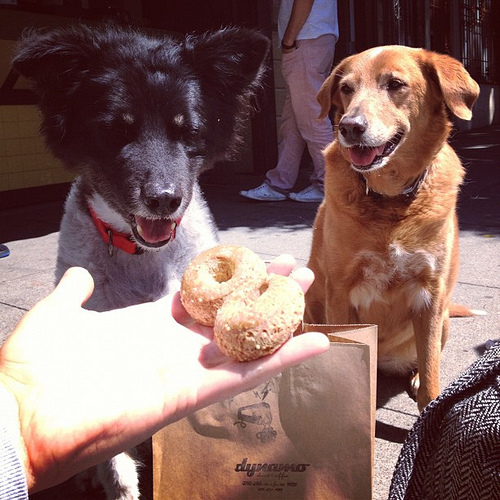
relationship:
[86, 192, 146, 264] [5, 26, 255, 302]
collar on dog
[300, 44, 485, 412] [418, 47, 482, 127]
dog with h ear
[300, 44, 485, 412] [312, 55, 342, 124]
dog with h ear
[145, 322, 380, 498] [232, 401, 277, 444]
bag with a logo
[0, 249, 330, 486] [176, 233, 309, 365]
hand with dog treats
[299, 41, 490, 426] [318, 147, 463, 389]
dog with fur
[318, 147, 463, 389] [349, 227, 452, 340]
fur on its chest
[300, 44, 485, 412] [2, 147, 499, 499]
dog sitting on a sidewalk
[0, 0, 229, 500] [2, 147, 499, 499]
dog sitting on a sidewalk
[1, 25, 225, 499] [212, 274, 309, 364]
dog looking at donut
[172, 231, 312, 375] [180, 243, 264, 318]
donut looking at donut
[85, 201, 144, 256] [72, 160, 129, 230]
collar around dog's neck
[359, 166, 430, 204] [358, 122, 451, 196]
collar around dog's neck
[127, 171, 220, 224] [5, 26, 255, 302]
nose of a dog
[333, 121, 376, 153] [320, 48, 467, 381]
nose of a dog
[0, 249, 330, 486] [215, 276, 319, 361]
hand holding donut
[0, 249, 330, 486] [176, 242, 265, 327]
hand holding donut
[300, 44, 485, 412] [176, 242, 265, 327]
dog looking at donut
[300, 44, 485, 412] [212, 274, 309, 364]
dog looking at donut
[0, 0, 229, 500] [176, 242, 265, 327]
dog looking at donut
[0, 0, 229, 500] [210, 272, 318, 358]
dog looking at donut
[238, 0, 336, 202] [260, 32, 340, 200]
man wearing brown pants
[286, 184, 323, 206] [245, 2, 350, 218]
shoe on man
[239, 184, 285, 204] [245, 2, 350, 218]
shoe on man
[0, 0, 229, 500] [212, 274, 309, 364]
dog looking at donut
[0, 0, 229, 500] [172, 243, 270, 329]
dog looking at donut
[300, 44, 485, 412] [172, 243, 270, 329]
dog looking at donut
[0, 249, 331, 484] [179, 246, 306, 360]
hand holding food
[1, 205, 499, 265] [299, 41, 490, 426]
shadow line behind dog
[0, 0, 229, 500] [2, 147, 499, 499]
dog on sidewalk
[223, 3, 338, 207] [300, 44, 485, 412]
man walking behind dog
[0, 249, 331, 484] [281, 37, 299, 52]
hand has a wristband